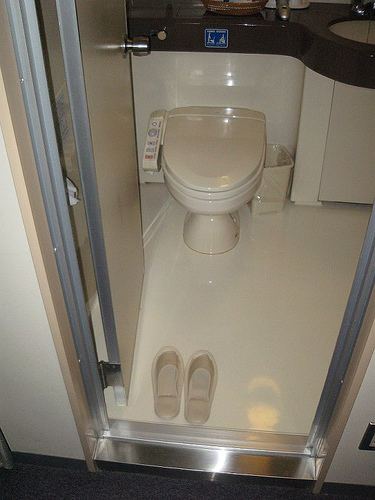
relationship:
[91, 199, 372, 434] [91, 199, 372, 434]
floor of floor